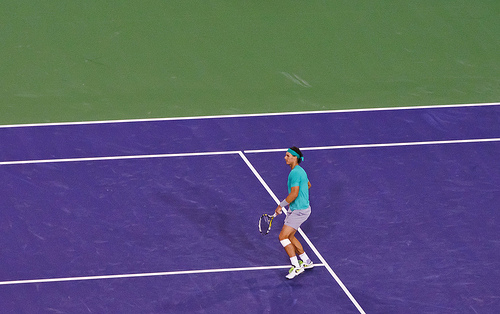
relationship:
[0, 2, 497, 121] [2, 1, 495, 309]
bounds on court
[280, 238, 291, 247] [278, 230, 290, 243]
band on knee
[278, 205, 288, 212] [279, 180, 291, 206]
wristband on arm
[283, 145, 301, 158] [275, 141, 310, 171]
headband on head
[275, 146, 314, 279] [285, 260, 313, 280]
man has shoe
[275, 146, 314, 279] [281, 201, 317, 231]
man has shorts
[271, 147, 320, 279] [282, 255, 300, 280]
man wears shoe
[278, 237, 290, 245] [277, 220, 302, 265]
band on leg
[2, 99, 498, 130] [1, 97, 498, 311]
line on court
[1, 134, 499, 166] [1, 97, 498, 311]
line on court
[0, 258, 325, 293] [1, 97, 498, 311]
line on court